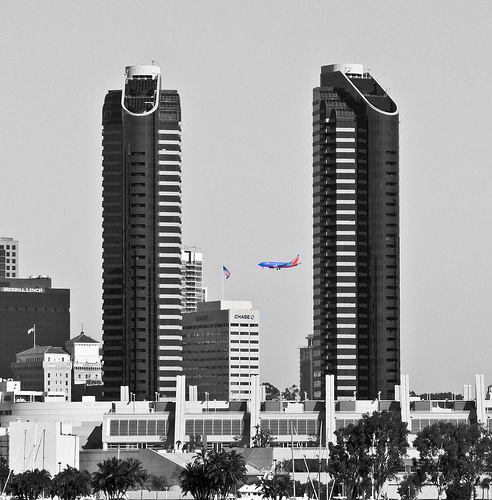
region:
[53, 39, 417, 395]
two alike big tower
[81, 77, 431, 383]
Airplane in between two big towers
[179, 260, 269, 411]
Chase building in between two towers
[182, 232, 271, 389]
Flag on top of Chase building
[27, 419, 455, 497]
Trees in front of the buildings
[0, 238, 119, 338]
Building with label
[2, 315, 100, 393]
two smaller buildings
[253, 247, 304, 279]
blue and red airport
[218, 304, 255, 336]
Chase logo on top of the building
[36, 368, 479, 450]
stadium in front of the two towers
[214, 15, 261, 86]
part of the sky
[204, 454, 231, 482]
part of some trees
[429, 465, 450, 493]
part of some tree branches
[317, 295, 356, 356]
side of a building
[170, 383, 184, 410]
part of a building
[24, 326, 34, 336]
part of a flag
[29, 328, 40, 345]
part of a post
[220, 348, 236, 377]
edge of a building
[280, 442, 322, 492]
part of some posts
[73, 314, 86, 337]
part of a tip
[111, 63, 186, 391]
large multi story building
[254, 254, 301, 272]
Blue and red airplane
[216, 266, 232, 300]
american flag on top of building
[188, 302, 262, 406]
large Chase bank building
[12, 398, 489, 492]
large short and long building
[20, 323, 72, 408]
small building with a flag on top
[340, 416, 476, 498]
a row of deciduous trees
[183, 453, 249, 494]
small group of palm trees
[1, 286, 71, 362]
large merril lynch building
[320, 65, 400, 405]
large black skyscraper building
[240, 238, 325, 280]
The plane is flying.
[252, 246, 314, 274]
The plane is blue and red.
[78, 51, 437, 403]
The plane is seen between two buildings.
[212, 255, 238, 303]
The American flag is atop the building.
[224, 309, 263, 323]
The brand name Chase is on the building.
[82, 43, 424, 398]
The two skyscrapers are identical.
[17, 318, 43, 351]
A flag is atop another building.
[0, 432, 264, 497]
Trees are in front of the buildings.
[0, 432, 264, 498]
The trees are palm trees.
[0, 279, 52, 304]
The name Merrill Lynch is on the building.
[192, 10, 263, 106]
this is the sky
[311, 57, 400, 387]
this is a building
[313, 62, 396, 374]
the building is tall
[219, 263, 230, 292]
this is a flag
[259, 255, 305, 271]
this is a jet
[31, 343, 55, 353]
this is a roof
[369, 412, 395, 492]
this is a tree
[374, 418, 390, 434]
the tree has green leaves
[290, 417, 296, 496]
this is a pole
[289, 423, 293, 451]
the pole is white in color